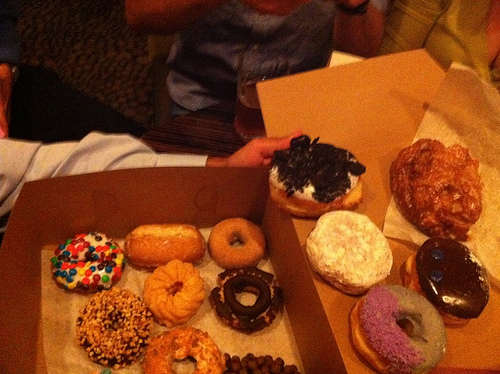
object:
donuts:
[138, 258, 209, 330]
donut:
[403, 236, 495, 331]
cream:
[458, 251, 483, 277]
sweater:
[0, 132, 205, 234]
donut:
[269, 132, 365, 215]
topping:
[272, 132, 364, 200]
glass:
[230, 42, 289, 144]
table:
[149, 107, 252, 151]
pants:
[5, 66, 144, 140]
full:
[236, 85, 267, 131]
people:
[0, 1, 164, 139]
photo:
[4, 7, 496, 365]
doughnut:
[144, 257, 208, 327]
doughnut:
[390, 135, 490, 241]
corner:
[381, 43, 499, 161]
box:
[1, 47, 494, 369]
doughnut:
[77, 287, 154, 367]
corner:
[2, 175, 118, 292]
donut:
[51, 229, 123, 292]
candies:
[67, 267, 78, 276]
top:
[50, 232, 123, 289]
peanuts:
[90, 315, 104, 325]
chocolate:
[214, 298, 234, 319]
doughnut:
[204, 264, 286, 334]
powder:
[302, 209, 392, 298]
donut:
[306, 208, 395, 292]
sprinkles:
[358, 283, 420, 373]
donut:
[350, 284, 448, 372]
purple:
[363, 284, 399, 370]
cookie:
[184, 334, 199, 348]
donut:
[148, 325, 223, 373]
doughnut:
[122, 221, 208, 273]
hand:
[206, 133, 303, 165]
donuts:
[217, 350, 297, 373]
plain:
[205, 214, 268, 271]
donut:
[207, 215, 267, 270]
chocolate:
[440, 244, 470, 304]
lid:
[256, 34, 499, 374]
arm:
[0, 132, 221, 206]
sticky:
[386, 138, 482, 246]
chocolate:
[76, 337, 95, 349]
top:
[78, 286, 147, 364]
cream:
[84, 234, 107, 248]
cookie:
[310, 171, 335, 200]